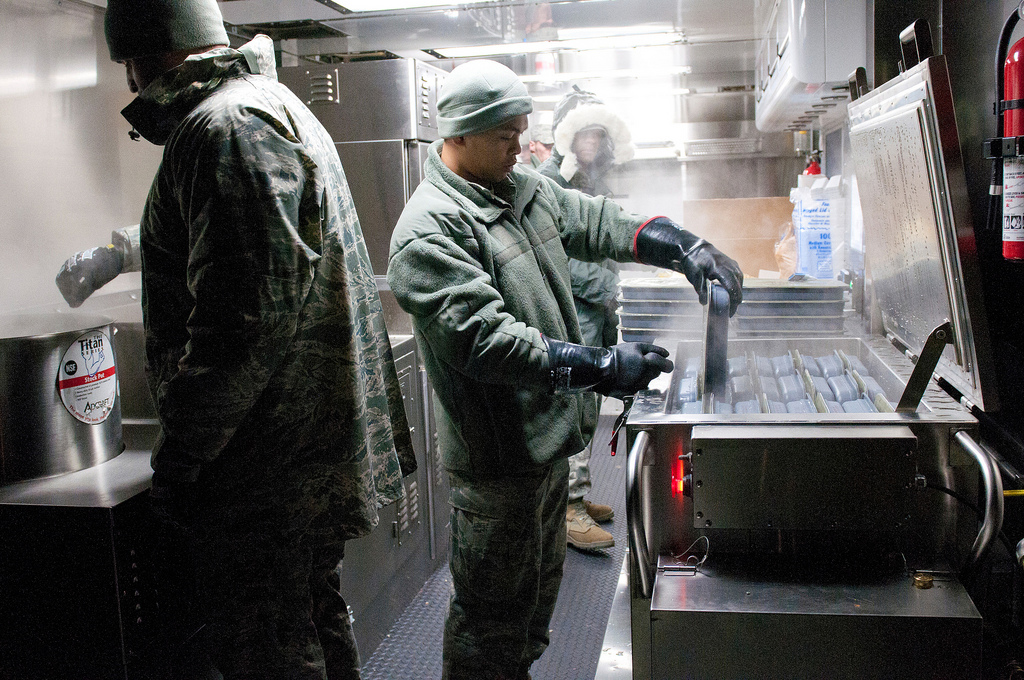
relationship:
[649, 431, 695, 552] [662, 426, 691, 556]
glow of glow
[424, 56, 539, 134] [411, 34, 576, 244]
beanie on man